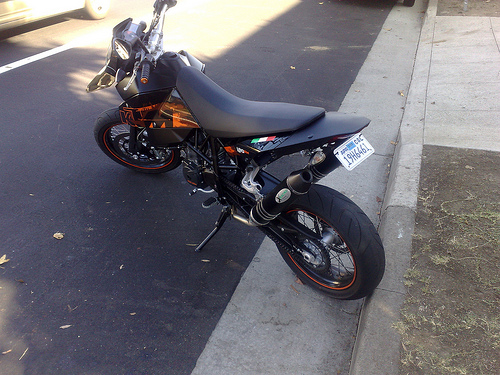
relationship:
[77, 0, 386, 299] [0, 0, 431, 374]
motorcycle parked on road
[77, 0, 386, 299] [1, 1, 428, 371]
motorcycle parked on street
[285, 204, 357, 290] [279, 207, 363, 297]
stripe on rim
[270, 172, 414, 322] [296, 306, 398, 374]
tire against curb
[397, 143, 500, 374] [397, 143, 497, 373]
dirt by dirt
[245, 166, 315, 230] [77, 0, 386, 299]
muffler on motorcycle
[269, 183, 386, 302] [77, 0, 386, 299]
back wheel of motorcycle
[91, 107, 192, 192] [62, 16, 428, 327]
wheel of motorcycle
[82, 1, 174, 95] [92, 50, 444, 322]
handlebars of motorcycle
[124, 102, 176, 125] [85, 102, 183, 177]
red strip on front wheel